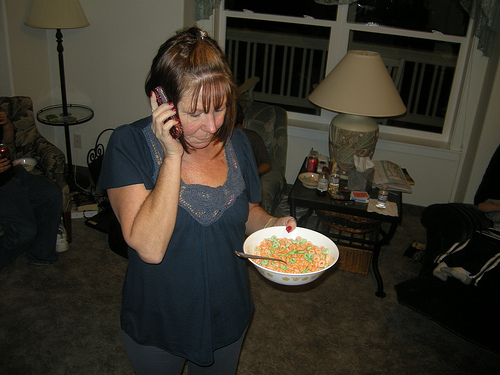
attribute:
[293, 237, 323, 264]
cereal — Green, Orange , Pink 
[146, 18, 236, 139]
hair — brown 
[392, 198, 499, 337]
chair — brown 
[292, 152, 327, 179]
can — red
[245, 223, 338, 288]
bowl — white, large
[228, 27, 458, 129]
wooden fence — white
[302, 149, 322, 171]
can — red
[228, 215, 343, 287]
bowl — full 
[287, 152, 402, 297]
table — small, black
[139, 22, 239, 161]
hair — brown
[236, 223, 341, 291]
bowl — round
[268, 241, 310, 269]
cereal — round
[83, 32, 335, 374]
woman — looking down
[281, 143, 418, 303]
stand — wooden 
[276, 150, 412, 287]
table — small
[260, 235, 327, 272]
cereal — Apple Jacks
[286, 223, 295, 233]
nail polish — red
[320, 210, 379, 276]
basket — wicker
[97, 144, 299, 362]
shirt — blue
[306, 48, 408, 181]
lamp — large, table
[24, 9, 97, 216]
floor lamp — black 